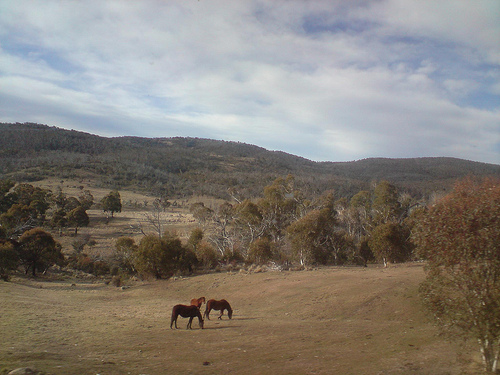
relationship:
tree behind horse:
[177, 245, 200, 277] [187, 293, 209, 315]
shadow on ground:
[189, 322, 243, 331] [1, 264, 499, 374]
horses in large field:
[167, 294, 236, 333] [1, 170, 499, 374]